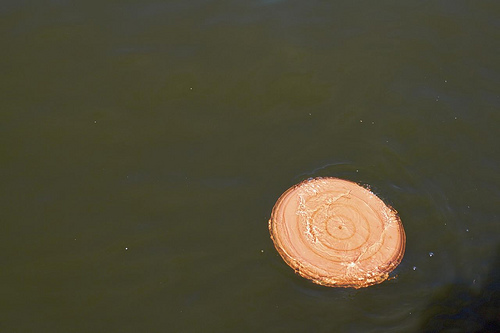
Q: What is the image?
A: Log.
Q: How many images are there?
A: One.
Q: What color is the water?
A: Green.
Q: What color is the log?
A: Brown.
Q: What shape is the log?
A: Circle.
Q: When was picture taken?
A: Daytime.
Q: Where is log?
A: In the water.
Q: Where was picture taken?
A: On water.